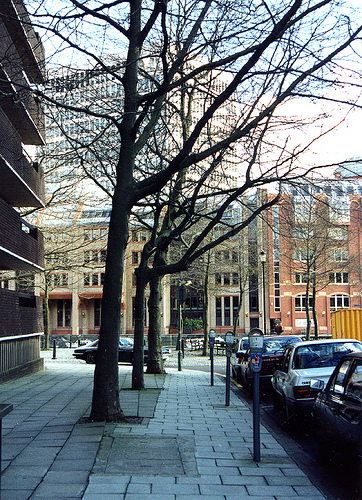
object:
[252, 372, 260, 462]
pole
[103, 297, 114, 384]
bark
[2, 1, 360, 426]
tree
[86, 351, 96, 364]
tire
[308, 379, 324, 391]
mirror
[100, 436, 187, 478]
stone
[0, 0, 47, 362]
building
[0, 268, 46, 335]
porch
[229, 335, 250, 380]
cars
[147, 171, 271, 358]
tree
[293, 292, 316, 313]
windows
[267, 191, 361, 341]
building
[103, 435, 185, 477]
panels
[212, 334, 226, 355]
table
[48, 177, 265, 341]
building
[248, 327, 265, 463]
meter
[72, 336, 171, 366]
car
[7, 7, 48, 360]
space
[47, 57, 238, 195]
building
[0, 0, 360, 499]
city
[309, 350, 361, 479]
car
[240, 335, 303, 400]
car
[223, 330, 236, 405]
parking meter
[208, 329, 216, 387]
parking meter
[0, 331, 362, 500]
street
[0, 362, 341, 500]
sidewalk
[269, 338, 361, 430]
car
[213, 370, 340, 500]
curb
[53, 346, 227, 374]
street corner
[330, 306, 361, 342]
container